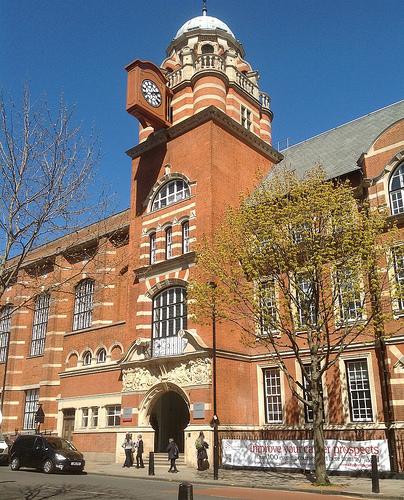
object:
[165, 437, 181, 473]
people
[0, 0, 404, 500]
outdoors